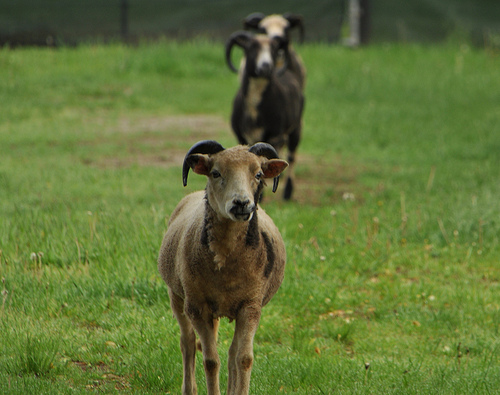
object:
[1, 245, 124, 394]
field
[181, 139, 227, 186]
horn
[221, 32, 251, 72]
horn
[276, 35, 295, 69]
horn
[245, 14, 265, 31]
horn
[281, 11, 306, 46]
horn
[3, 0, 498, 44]
fence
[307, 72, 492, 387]
field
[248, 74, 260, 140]
marking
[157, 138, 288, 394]
brown ram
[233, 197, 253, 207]
nose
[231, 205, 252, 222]
lips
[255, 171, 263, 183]
eye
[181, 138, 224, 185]
black horn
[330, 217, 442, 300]
flower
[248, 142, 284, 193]
horn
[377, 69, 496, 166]
grass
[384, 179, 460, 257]
grass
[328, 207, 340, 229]
flower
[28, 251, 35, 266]
flower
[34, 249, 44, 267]
flower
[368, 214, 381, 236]
flower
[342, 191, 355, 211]
flower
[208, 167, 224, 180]
eye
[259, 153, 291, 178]
ear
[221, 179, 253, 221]
white muzzle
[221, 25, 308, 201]
brown goat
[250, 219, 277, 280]
marking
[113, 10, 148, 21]
line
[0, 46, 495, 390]
flowers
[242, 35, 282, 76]
face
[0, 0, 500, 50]
privacy screen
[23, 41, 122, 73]
ground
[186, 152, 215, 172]
ear